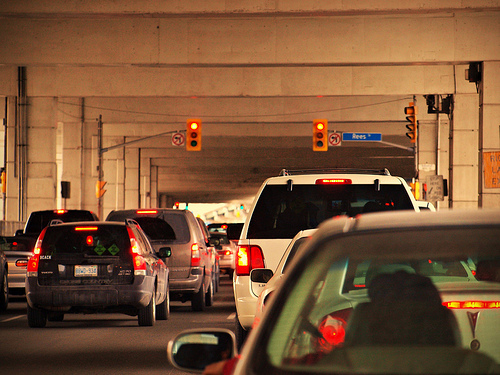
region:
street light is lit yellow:
[281, 83, 432, 190]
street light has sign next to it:
[305, 111, 360, 153]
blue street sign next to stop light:
[309, 115, 391, 155]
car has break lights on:
[19, 200, 169, 325]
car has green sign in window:
[76, 221, 128, 269]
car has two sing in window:
[46, 207, 143, 287]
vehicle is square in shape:
[224, 160, 421, 329]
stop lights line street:
[387, 92, 454, 217]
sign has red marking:
[161, 127, 187, 151]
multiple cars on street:
[12, 135, 489, 372]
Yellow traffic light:
[185, 115, 202, 153]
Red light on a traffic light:
[189, 119, 199, 129]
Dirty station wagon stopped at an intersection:
[23, 215, 170, 325]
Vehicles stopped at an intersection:
[0, 165, 497, 374]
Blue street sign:
[340, 128, 385, 144]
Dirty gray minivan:
[103, 206, 213, 308]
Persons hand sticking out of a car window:
[198, 356, 232, 373]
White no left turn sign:
[327, 130, 342, 145]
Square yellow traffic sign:
[481, 150, 498, 192]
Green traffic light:
[235, 203, 245, 213]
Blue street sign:
[339, 133, 386, 140]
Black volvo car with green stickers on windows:
[19, 216, 173, 323]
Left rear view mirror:
[168, 326, 235, 370]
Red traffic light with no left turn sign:
[169, 115, 204, 150]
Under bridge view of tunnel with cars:
[2, 65, 499, 374]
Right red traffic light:
[312, 119, 330, 149]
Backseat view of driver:
[339, 266, 466, 346]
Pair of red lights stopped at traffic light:
[32, 225, 149, 273]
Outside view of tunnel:
[170, 201, 259, 229]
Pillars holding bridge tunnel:
[0, 89, 174, 239]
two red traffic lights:
[162, 115, 354, 152]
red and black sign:
[165, 131, 192, 161]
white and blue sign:
[337, 127, 388, 144]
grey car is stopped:
[31, 216, 179, 316]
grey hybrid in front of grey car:
[112, 190, 215, 295]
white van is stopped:
[219, 178, 427, 327]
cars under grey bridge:
[12, 67, 483, 289]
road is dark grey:
[15, 306, 232, 373]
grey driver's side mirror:
[176, 324, 259, 374]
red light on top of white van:
[315, 174, 345, 196]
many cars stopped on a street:
[26, 163, 476, 350]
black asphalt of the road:
[48, 335, 114, 371]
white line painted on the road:
[216, 296, 239, 322]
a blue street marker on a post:
[343, 123, 377, 141]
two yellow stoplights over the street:
[175, 111, 334, 153]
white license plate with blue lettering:
[66, 261, 102, 282]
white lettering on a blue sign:
[348, 134, 375, 139]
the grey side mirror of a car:
[165, 330, 240, 366]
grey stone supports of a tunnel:
[161, 12, 347, 97]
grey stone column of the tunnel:
[16, 111, 55, 212]